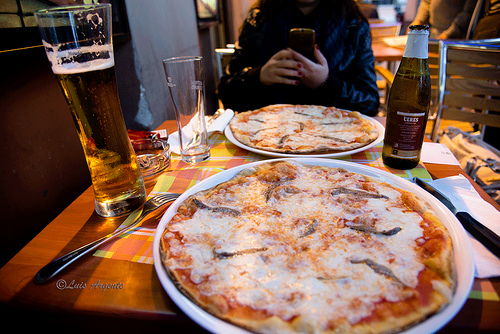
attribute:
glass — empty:
[158, 51, 220, 156]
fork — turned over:
[33, 190, 179, 288]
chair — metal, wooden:
[457, 49, 482, 134]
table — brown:
[3, 114, 497, 332]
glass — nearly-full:
[32, 0, 150, 219]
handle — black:
[459, 207, 498, 252]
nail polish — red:
[284, 47, 309, 88]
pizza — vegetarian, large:
[225, 101, 380, 155]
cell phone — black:
[273, 28, 327, 77]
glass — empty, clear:
[167, 60, 215, 162]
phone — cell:
[276, 52, 349, 94]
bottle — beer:
[378, 25, 434, 172]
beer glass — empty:
[128, 28, 250, 182]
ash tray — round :
[133, 122, 183, 167]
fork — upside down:
[15, 187, 180, 277]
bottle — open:
[382, 16, 444, 165]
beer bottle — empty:
[380, 25, 435, 167]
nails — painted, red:
[293, 52, 297, 70]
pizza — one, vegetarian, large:
[159, 160, 456, 332]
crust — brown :
[427, 218, 454, 303]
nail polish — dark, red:
[292, 57, 306, 79]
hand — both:
[261, 46, 297, 87]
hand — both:
[293, 49, 329, 85]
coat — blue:
[212, 0, 380, 114]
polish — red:
[285, 63, 306, 82]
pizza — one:
[229, 105, 377, 153]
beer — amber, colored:
[52, 65, 142, 196]